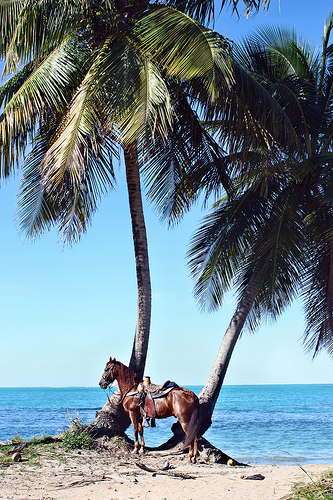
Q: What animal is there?
A: Horse.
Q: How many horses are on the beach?
A: One.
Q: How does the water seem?
A: Calm.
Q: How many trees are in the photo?
A: Two.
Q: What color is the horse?
A: Brown.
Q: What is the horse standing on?
A: Sand.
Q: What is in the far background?
A: Water.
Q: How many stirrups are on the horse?
A: Two.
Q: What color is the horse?
A: Brown.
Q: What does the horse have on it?
A: A saddle.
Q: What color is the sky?
A: Blue.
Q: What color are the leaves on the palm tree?
A: Green.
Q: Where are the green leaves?
A: On the palm tree?.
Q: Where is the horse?
A: On the beach.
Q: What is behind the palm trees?
A: The ocean.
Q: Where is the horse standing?
A: On a sandy beach.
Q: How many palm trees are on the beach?
A: 2.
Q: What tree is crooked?
A: The small one.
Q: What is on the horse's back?
A: Saddle.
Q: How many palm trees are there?
A: 2.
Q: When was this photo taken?
A: Daytime.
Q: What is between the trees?
A: Horse.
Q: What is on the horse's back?
A: Saddle.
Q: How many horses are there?
A: One.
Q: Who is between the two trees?
A: Horse.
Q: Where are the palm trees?
A: By the horse.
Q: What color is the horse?
A: Brown.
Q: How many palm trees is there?
A: Two.